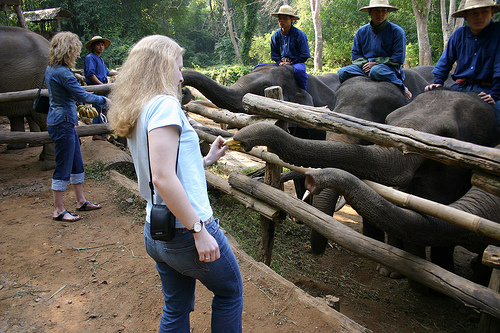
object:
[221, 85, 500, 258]
elephant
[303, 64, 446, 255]
elephant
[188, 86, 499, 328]
fence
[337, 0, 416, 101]
man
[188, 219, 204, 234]
watch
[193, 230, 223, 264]
right hand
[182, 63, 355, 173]
elephant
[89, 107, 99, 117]
bananas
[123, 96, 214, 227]
t-shirt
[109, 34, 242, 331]
lady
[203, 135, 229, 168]
hand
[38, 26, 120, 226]
woman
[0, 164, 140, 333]
dirt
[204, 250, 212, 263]
finger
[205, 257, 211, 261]
ring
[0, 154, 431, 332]
ground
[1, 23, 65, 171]
elephant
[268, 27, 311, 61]
shirt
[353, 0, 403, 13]
hat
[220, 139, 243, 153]
food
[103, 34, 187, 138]
blonde hair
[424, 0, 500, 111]
person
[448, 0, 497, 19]
hat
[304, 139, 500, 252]
elephant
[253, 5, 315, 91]
man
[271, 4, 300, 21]
hat